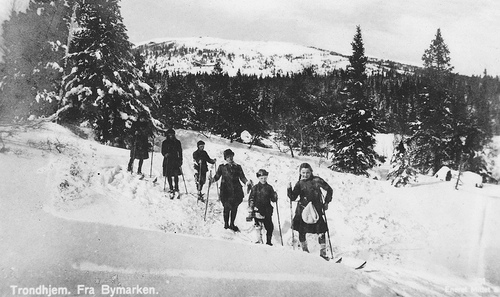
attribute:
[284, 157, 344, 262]
girl — young